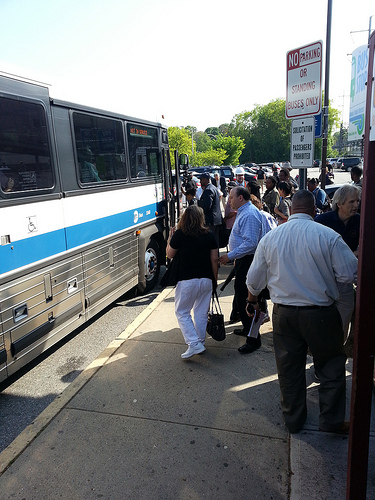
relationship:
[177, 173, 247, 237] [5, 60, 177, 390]
people getting in bus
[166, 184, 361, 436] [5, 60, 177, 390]
people getting in bus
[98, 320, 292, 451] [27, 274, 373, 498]
cracks in sidewalk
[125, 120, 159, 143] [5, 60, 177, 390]
screen on bus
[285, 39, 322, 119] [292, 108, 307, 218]
sign on post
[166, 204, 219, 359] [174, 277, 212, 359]
person in pants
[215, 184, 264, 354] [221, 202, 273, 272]
man in button down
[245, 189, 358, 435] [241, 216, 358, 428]
business clothes in business clothes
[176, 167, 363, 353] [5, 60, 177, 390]
crowd of people gather to get on bus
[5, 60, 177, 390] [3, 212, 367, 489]
bus pulls into bus stop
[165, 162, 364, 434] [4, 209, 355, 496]
crowd standing on sidewalk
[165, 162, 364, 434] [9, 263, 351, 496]
crowd standing on sidewalk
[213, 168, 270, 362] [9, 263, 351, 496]
person standing on sidewalk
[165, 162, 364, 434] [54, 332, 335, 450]
crowd standing on sidewalk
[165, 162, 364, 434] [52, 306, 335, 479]
crowd standing on sidewalk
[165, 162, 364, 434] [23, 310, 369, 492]
crowd standing on sidewalk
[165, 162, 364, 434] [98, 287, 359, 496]
crowd standing on sidewalk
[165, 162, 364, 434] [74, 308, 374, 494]
crowd standing on sidewalk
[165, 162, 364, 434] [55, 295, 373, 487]
crowd standing on sidewalk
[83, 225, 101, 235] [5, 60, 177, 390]
blue stripe on bus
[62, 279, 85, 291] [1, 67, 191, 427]
light on bus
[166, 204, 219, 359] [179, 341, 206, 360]
person has shoes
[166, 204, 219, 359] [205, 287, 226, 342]
person carrying bag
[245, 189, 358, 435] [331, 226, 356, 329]
business clothes holding papers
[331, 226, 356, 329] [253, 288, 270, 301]
papers in hand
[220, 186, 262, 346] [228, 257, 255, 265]
man wearing belt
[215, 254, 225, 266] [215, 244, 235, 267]
watch on wrist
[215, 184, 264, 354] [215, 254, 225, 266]
man has watch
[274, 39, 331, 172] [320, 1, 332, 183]
sign on pole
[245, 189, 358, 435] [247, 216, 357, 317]
business clothes has shirt